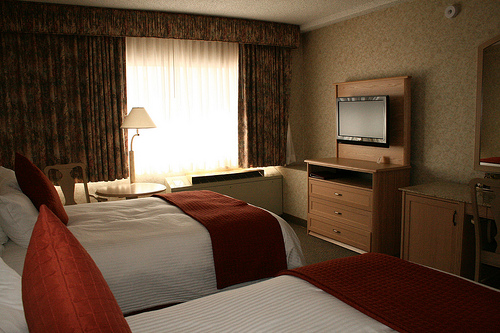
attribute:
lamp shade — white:
[116, 104, 158, 187]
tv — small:
[334, 90, 406, 145]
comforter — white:
[98, 196, 190, 276]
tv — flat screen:
[324, 91, 399, 158]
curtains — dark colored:
[3, 36, 118, 143]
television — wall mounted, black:
[335, 92, 393, 149]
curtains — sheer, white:
[127, 36, 237, 180]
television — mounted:
[335, 92, 390, 146]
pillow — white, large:
[0, 190, 42, 247]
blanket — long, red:
[151, 186, 291, 289]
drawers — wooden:
[300, 171, 381, 252]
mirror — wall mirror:
[473, 33, 499, 175]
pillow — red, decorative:
[20, 206, 132, 331]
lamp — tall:
[117, 104, 157, 189]